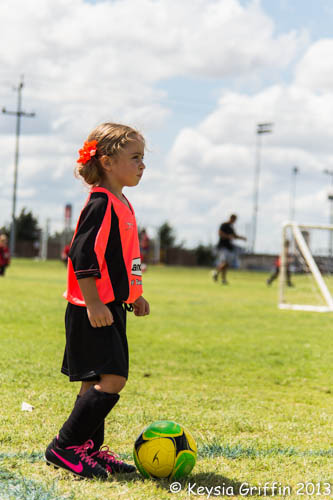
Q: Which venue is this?
A: This is a field.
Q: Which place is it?
A: It is a field.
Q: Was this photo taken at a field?
A: Yes, it was taken in a field.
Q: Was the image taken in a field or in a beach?
A: It was taken at a field.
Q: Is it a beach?
A: No, it is a field.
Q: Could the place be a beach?
A: No, it is a field.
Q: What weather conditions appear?
A: It is cloudy.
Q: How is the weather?
A: It is cloudy.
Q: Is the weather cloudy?
A: Yes, it is cloudy.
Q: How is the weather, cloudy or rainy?
A: It is cloudy.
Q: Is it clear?
A: No, it is cloudy.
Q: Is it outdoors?
A: Yes, it is outdoors.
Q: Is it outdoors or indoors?
A: It is outdoors.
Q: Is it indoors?
A: No, it is outdoors.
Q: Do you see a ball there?
A: Yes, there is a ball.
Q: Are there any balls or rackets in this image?
A: Yes, there is a ball.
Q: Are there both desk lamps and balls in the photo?
A: No, there is a ball but no desk lamps.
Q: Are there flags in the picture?
A: No, there are no flags.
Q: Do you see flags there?
A: No, there are no flags.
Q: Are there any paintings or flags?
A: No, there are no flags or paintings.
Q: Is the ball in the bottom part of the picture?
A: Yes, the ball is in the bottom of the image.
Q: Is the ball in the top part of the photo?
A: No, the ball is in the bottom of the image.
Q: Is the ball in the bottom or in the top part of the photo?
A: The ball is in the bottom of the image.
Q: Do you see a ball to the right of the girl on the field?
A: Yes, there is a ball to the right of the girl.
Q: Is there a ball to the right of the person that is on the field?
A: Yes, there is a ball to the right of the girl.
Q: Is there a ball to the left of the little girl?
A: No, the ball is to the right of the girl.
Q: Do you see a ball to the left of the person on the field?
A: No, the ball is to the right of the girl.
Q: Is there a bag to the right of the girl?
A: No, there is a ball to the right of the girl.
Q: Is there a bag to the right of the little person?
A: No, there is a ball to the right of the girl.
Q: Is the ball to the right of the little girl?
A: Yes, the ball is to the right of the girl.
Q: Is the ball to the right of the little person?
A: Yes, the ball is to the right of the girl.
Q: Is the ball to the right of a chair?
A: No, the ball is to the right of the girl.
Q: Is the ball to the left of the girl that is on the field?
A: No, the ball is to the right of the girl.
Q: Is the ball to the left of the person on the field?
A: No, the ball is to the right of the girl.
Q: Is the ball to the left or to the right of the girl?
A: The ball is to the right of the girl.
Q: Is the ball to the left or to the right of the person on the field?
A: The ball is to the right of the girl.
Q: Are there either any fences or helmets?
A: No, there are no fences or helmets.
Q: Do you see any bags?
A: No, there are no bags.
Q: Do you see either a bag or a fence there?
A: No, there are no bags or fences.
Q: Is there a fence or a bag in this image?
A: No, there are no bags or fences.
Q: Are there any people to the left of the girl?
A: Yes, there is a person to the left of the girl.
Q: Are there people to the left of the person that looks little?
A: Yes, there is a person to the left of the girl.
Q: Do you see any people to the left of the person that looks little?
A: Yes, there is a person to the left of the girl.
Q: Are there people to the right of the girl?
A: No, the person is to the left of the girl.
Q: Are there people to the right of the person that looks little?
A: No, the person is to the left of the girl.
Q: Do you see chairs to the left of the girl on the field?
A: No, there is a person to the left of the girl.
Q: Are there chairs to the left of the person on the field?
A: No, there is a person to the left of the girl.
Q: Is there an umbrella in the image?
A: No, there are no umbrellas.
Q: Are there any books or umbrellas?
A: No, there are no umbrellas or books.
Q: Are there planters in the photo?
A: No, there are no planters.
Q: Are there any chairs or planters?
A: No, there are no planters or chairs.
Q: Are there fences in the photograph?
A: No, there are no fences.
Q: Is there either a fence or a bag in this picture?
A: No, there are no fences or bags.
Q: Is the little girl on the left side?
A: Yes, the girl is on the left of the image.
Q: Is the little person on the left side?
A: Yes, the girl is on the left of the image.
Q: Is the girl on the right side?
A: No, the girl is on the left of the image.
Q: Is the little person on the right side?
A: No, the girl is on the left of the image.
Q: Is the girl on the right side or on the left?
A: The girl is on the left of the image.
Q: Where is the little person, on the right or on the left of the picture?
A: The girl is on the left of the image.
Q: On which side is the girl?
A: The girl is on the left of the image.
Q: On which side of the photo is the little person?
A: The girl is on the left of the image.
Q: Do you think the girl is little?
A: Yes, the girl is little.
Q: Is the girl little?
A: Yes, the girl is little.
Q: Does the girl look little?
A: Yes, the girl is little.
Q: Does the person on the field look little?
A: Yes, the girl is little.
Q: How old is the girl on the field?
A: The girl is little.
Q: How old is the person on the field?
A: The girl is little.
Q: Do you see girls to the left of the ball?
A: Yes, there is a girl to the left of the ball.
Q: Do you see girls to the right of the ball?
A: No, the girl is to the left of the ball.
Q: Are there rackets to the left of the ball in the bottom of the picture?
A: No, there is a girl to the left of the ball.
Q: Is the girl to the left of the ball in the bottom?
A: Yes, the girl is to the left of the ball.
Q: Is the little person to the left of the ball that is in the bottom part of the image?
A: Yes, the girl is to the left of the ball.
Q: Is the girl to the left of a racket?
A: No, the girl is to the left of the ball.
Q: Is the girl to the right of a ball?
A: No, the girl is to the left of a ball.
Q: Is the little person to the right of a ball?
A: No, the girl is to the left of a ball.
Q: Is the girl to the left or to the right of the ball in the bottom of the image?
A: The girl is to the left of the ball.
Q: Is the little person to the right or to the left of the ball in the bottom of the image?
A: The girl is to the left of the ball.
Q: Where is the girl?
A: The girl is on the field.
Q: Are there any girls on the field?
A: Yes, there is a girl on the field.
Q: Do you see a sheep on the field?
A: No, there is a girl on the field.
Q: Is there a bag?
A: No, there are no bags.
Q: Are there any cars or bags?
A: No, there are no bags or cars.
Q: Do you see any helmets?
A: No, there are no helmets.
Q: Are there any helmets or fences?
A: No, there are no helmets or fences.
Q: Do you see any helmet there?
A: No, there are no helmets.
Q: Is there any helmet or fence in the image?
A: No, there are no helmets or fences.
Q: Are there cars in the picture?
A: No, there are no cars.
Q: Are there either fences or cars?
A: No, there are no cars or fences.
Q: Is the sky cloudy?
A: Yes, the sky is cloudy.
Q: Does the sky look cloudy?
A: Yes, the sky is cloudy.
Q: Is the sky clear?
A: No, the sky is cloudy.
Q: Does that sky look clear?
A: No, the sky is cloudy.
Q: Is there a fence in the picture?
A: No, there are no fences.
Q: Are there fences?
A: No, there are no fences.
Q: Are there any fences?
A: No, there are no fences.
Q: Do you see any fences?
A: No, there are no fences.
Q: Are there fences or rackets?
A: No, there are no fences or rackets.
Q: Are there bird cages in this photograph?
A: No, there are no bird cages.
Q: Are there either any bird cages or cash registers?
A: No, there are no bird cages or cash registers.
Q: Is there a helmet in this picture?
A: No, there are no helmets.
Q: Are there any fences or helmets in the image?
A: No, there are no helmets or fences.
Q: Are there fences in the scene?
A: No, there are no fences.